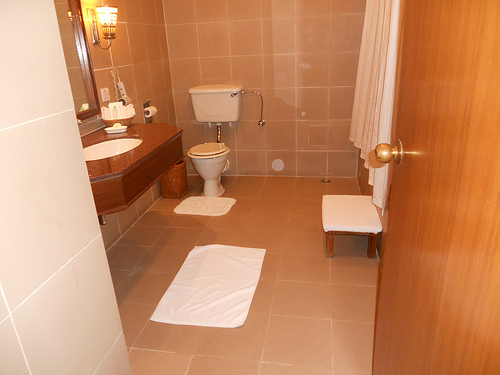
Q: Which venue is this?
A: This is a bathroom.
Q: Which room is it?
A: It is a bathroom.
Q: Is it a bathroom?
A: Yes, it is a bathroom.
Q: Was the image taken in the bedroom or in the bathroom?
A: It was taken at the bathroom.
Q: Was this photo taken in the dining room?
A: No, the picture was taken in the bathroom.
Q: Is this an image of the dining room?
A: No, the picture is showing the bathroom.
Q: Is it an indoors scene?
A: Yes, it is indoors.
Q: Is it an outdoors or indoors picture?
A: It is indoors.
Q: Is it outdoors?
A: No, it is indoors.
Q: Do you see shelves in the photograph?
A: No, there are no shelves.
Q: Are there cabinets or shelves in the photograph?
A: No, there are no shelves or cabinets.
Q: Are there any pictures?
A: No, there are no pictures.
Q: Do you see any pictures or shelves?
A: No, there are no pictures or shelves.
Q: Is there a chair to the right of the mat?
A: No, there is a curtain to the right of the mat.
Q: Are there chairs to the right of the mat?
A: No, there is a curtain to the right of the mat.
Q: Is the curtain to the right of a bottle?
A: No, the curtain is to the right of a mat.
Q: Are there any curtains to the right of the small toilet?
A: Yes, there is a curtain to the right of the toilet.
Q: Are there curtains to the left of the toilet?
A: No, the curtain is to the right of the toilet.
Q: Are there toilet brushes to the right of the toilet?
A: No, there is a curtain to the right of the toilet.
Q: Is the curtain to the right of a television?
A: No, the curtain is to the right of the toilet.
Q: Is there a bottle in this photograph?
A: No, there are no bottles.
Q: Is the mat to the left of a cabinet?
A: No, the mat is to the left of the curtain.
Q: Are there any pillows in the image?
A: No, there are no pillows.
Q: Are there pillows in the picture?
A: No, there are no pillows.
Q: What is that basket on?
A: The basket is on the counter.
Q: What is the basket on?
A: The basket is on the counter.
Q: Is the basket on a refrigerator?
A: No, the basket is on the counter.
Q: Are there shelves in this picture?
A: No, there are no shelves.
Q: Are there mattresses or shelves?
A: No, there are no shelves or mattresses.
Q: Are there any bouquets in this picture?
A: No, there are no bouquets.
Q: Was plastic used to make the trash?
A: No, the trash is made of wicker.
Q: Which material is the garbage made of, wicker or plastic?
A: The garbage is made of wicker.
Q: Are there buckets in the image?
A: No, there are no buckets.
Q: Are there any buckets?
A: No, there are no buckets.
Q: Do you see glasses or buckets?
A: No, there are no buckets or glasses.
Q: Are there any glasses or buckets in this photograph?
A: No, there are no buckets or glasses.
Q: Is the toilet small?
A: Yes, the toilet is small.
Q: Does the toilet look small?
A: Yes, the toilet is small.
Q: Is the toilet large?
A: No, the toilet is small.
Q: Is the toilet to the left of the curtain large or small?
A: The toilet is small.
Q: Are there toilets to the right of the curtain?
A: No, the toilet is to the left of the curtain.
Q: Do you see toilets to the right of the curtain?
A: No, the toilet is to the left of the curtain.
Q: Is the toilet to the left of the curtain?
A: Yes, the toilet is to the left of the curtain.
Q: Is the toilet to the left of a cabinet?
A: No, the toilet is to the left of the curtain.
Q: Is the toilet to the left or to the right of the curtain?
A: The toilet is to the left of the curtain.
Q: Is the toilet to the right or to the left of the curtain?
A: The toilet is to the left of the curtain.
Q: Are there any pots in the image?
A: No, there are no pots.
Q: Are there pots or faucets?
A: No, there are no pots or faucets.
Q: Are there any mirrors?
A: Yes, there is a mirror.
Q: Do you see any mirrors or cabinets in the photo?
A: Yes, there is a mirror.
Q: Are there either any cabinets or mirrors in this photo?
A: Yes, there is a mirror.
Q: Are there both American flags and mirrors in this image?
A: No, there is a mirror but no American flags.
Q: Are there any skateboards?
A: No, there are no skateboards.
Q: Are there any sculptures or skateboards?
A: No, there are no skateboards or sculptures.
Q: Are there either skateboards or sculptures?
A: No, there are no skateboards or sculptures.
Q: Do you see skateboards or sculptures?
A: No, there are no skateboards or sculptures.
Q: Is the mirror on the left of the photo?
A: Yes, the mirror is on the left of the image.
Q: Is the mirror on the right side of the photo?
A: No, the mirror is on the left of the image.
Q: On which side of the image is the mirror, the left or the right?
A: The mirror is on the left of the image.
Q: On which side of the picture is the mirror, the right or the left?
A: The mirror is on the left of the image.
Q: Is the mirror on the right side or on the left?
A: The mirror is on the left of the image.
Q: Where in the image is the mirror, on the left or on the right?
A: The mirror is on the left of the image.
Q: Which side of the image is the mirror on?
A: The mirror is on the left of the image.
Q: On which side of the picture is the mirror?
A: The mirror is on the left of the image.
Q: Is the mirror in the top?
A: Yes, the mirror is in the top of the image.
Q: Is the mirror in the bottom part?
A: No, the mirror is in the top of the image.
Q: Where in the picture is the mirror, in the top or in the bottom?
A: The mirror is in the top of the image.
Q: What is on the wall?
A: The mirror is on the wall.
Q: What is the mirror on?
A: The mirror is on the wall.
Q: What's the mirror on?
A: The mirror is on the wall.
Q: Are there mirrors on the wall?
A: Yes, there is a mirror on the wall.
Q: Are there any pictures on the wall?
A: No, there is a mirror on the wall.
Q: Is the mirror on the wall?
A: Yes, the mirror is on the wall.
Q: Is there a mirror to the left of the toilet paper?
A: Yes, there is a mirror to the left of the toilet paper.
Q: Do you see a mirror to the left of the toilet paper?
A: Yes, there is a mirror to the left of the toilet paper.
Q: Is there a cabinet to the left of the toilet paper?
A: No, there is a mirror to the left of the toilet paper.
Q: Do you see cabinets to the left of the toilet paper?
A: No, there is a mirror to the left of the toilet paper.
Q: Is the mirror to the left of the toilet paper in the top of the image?
A: Yes, the mirror is to the left of the toilet paper.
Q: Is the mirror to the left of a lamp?
A: No, the mirror is to the left of the toilet paper.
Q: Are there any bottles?
A: No, there are no bottles.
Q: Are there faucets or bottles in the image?
A: No, there are no bottles or faucets.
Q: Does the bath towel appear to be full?
A: Yes, the bath towel is full.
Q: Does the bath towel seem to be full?
A: Yes, the bath towel is full.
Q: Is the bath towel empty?
A: No, the bath towel is full.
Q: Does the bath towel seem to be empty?
A: No, the bath towel is full.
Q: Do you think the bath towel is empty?
A: No, the bath towel is full.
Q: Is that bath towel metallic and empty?
A: No, the bath towel is metallic but full.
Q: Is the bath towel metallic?
A: Yes, the bath towel is metallic.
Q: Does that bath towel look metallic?
A: Yes, the bath towel is metallic.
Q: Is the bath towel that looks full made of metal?
A: Yes, the bath towel is made of metal.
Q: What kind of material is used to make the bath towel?
A: The bath towel is made of metal.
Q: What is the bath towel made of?
A: The bath towel is made of metal.